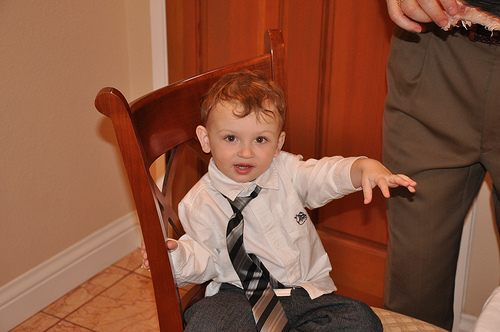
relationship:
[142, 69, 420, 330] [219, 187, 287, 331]
boy wearing tie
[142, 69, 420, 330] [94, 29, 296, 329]
boy sitting in chair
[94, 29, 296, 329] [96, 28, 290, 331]
chair made of wood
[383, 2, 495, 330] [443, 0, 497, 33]
man has food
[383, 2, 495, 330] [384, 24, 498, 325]
man wearing pants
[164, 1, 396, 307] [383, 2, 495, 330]
door behind man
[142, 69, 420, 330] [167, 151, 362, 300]
boy wearing shirt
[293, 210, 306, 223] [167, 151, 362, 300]
logo on shirt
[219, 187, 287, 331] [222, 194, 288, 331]
tie has stripes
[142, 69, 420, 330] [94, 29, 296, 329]
boy in chair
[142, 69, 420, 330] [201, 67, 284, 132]
boy has hair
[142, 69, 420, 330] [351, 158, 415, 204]
boy hold out hand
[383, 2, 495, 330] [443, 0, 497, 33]
man eating food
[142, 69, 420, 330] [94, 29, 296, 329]
boy sits in chair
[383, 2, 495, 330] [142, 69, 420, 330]
man beside boy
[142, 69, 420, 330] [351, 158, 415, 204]
boy has up hand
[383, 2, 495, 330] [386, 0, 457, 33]
man has hand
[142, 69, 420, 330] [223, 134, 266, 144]
boy has eyes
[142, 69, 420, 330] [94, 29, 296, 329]
boy holding on to chair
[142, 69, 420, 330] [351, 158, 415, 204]
boy has up h hand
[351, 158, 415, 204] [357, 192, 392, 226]
hand has shadow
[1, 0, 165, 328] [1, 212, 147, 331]
wall has baseboard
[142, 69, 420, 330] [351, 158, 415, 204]
boy holding out h hand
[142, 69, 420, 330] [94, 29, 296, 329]
boy holding onto chair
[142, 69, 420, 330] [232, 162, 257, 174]
boy has mouth